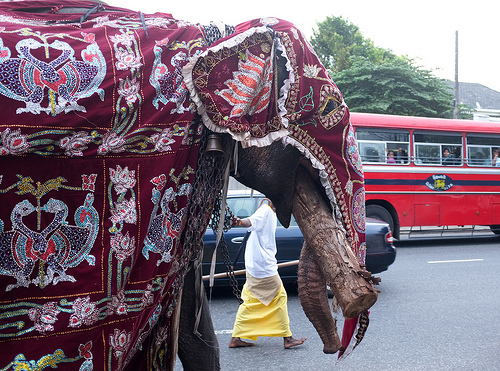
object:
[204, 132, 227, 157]
bell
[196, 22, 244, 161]
neck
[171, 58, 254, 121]
cover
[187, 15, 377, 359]
cloth hood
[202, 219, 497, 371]
street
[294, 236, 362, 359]
trunk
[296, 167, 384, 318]
log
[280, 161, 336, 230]
mouth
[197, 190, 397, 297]
car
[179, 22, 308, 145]
ear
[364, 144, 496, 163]
passengers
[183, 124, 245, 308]
chains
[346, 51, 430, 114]
leaves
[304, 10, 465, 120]
tree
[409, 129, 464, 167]
window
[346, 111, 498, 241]
bus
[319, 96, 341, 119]
eye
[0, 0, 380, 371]
hood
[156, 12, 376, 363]
elephant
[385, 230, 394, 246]
tail light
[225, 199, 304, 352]
man